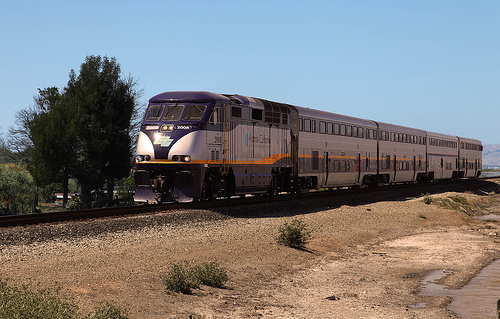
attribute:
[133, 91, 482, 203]
train — moving, silver, blue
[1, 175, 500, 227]
track — steel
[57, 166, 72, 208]
tree — covered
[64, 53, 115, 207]
tree — green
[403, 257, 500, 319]
water — pooled, puddled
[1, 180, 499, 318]
ground — dirt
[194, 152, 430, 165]
stripe — yellow, orange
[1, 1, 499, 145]
sky — blue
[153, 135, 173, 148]
letters — white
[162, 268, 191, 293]
bush — green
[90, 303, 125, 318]
bush — green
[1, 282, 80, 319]
bush — green